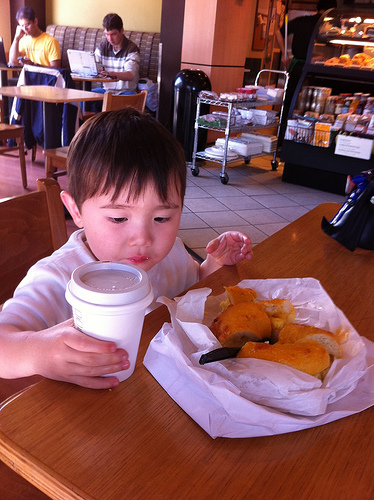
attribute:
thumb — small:
[203, 238, 216, 259]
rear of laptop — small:
[61, 46, 94, 79]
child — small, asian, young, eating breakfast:
[3, 98, 254, 390]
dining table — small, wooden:
[1, 196, 371, 499]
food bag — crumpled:
[142, 278, 372, 443]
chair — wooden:
[1, 174, 68, 305]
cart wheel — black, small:
[215, 170, 232, 189]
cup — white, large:
[65, 256, 159, 397]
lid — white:
[64, 262, 153, 314]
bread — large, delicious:
[205, 278, 332, 379]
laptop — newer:
[65, 48, 113, 85]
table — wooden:
[1, 64, 23, 87]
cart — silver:
[189, 64, 285, 190]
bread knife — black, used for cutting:
[198, 346, 239, 367]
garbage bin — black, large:
[172, 60, 211, 165]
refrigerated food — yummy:
[282, 18, 372, 158]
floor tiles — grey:
[182, 157, 346, 267]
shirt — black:
[281, 15, 320, 60]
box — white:
[211, 133, 263, 158]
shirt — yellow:
[11, 33, 61, 72]